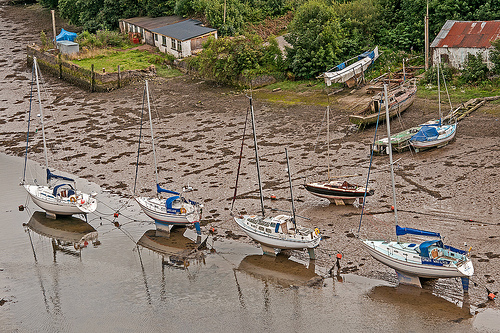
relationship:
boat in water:
[300, 173, 374, 208] [3, 6, 500, 306]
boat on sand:
[363, 77, 422, 126] [357, 85, 498, 138]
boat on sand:
[300, 173, 374, 208] [357, 85, 498, 138]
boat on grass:
[321, 44, 379, 94] [286, 57, 383, 94]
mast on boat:
[239, 111, 280, 221] [300, 173, 374, 208]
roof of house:
[435, 13, 500, 51] [425, 12, 500, 83]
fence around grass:
[25, 42, 137, 87] [84, 40, 152, 75]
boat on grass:
[321, 44, 379, 94] [84, 40, 152, 75]